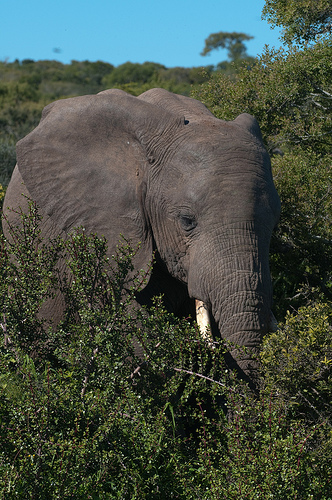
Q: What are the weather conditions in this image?
A: It is clear.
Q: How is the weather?
A: It is clear.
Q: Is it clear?
A: Yes, it is clear.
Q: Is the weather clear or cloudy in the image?
A: It is clear.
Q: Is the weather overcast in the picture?
A: No, it is clear.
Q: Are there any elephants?
A: Yes, there is an elephant.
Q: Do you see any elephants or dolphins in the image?
A: Yes, there is an elephant.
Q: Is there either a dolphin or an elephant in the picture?
A: Yes, there is an elephant.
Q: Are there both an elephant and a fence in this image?
A: No, there is an elephant but no fences.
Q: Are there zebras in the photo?
A: No, there are no zebras.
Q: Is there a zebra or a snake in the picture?
A: No, there are no zebras or snakes.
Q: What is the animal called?
A: The animal is an elephant.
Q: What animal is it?
A: The animal is an elephant.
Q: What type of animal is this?
A: This is an elephant.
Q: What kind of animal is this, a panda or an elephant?
A: This is an elephant.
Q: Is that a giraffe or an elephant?
A: That is an elephant.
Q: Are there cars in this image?
A: No, there are no cars.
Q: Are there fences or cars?
A: No, there are no cars or fences.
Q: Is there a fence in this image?
A: No, there are no fences.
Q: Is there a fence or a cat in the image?
A: No, there are no fences or cats.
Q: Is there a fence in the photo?
A: No, there are no fences.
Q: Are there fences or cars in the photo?
A: No, there are no fences or cars.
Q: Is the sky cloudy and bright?
A: No, the sky is bright but clear.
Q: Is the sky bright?
A: Yes, the sky is bright.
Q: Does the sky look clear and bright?
A: Yes, the sky is clear and bright.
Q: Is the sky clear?
A: Yes, the sky is clear.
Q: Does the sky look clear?
A: Yes, the sky is clear.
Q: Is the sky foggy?
A: No, the sky is clear.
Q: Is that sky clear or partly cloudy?
A: The sky is clear.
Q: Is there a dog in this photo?
A: No, there are no dogs.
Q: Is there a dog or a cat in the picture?
A: No, there are no dogs or cats.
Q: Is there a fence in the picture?
A: No, there are no fences.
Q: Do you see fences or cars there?
A: No, there are no fences or cars.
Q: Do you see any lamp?
A: No, there are no lamps.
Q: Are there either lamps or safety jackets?
A: No, there are no lamps or safety jackets.